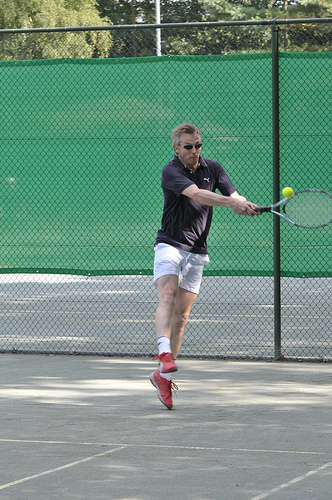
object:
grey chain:
[211, 94, 219, 102]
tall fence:
[0, 13, 332, 367]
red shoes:
[152, 348, 179, 374]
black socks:
[157, 342, 163, 346]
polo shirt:
[153, 154, 237, 255]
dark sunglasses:
[175, 143, 203, 150]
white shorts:
[153, 242, 210, 297]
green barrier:
[0, 54, 331, 66]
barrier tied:
[0, 266, 332, 278]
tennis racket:
[248, 188, 332, 230]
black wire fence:
[0, 17, 332, 363]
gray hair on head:
[171, 122, 201, 150]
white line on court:
[0, 438, 127, 446]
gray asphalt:
[0, 350, 332, 499]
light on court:
[73, 380, 154, 390]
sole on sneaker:
[160, 370, 178, 380]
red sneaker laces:
[172, 387, 178, 399]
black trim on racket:
[295, 222, 330, 229]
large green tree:
[2, 0, 116, 64]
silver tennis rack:
[270, 209, 294, 225]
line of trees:
[132, 0, 136, 57]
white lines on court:
[0, 445, 128, 489]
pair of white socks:
[161, 371, 172, 381]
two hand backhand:
[230, 191, 264, 217]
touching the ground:
[159, 398, 175, 411]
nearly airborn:
[139, 331, 194, 419]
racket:
[249, 187, 332, 234]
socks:
[157, 335, 174, 353]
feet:
[158, 349, 178, 374]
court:
[0, 350, 332, 500]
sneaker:
[148, 368, 179, 409]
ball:
[282, 186, 294, 200]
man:
[146, 120, 264, 413]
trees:
[0, 0, 115, 61]